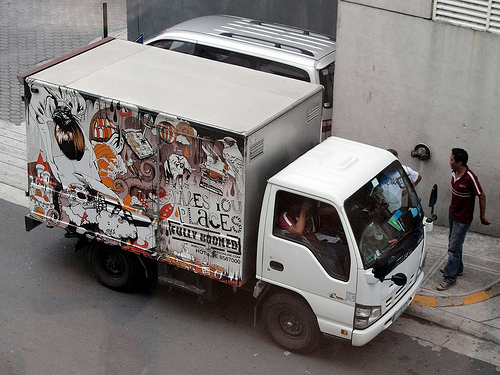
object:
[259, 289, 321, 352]
front tire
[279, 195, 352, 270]
man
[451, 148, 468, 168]
black hair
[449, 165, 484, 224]
red shirt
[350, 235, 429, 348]
bumper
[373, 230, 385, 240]
plate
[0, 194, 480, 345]
road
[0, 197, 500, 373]
ground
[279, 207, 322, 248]
shirt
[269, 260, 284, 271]
door handle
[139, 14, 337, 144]
van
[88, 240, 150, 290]
tire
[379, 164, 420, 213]
shirt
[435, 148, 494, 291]
man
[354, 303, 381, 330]
headlight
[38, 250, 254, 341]
street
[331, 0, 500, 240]
wall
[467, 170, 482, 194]
stripe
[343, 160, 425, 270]
window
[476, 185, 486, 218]
arm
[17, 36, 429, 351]
delivery truck